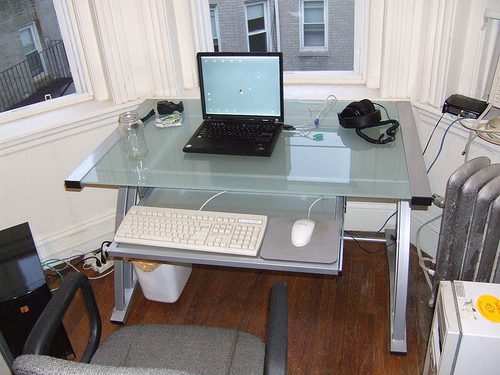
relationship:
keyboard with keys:
[112, 201, 274, 260] [141, 215, 170, 237]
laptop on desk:
[181, 50, 285, 156] [65, 96, 434, 356]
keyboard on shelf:
[113, 205, 269, 257] [111, 188, 346, 277]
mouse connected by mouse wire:
[293, 219, 313, 249] [300, 194, 336, 212]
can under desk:
[131, 261, 193, 304] [65, 96, 434, 356]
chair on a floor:
[11, 265, 296, 373] [2, 228, 444, 373]